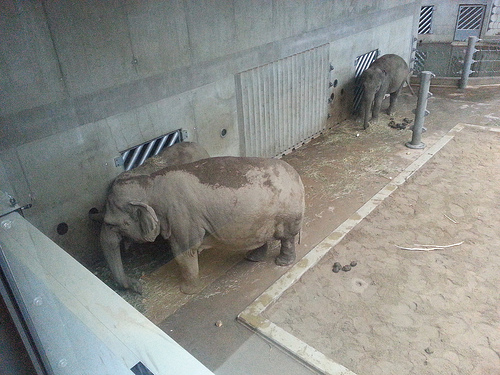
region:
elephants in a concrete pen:
[116, 52, 441, 296]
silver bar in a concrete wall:
[120, 133, 187, 163]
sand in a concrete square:
[320, 281, 495, 354]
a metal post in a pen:
[408, 71, 440, 151]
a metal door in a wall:
[233, 41, 335, 162]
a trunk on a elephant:
[96, 236, 128, 293]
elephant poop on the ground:
[317, 260, 364, 277]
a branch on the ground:
[398, 232, 475, 261]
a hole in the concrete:
[215, 122, 232, 141]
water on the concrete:
[318, 137, 396, 205]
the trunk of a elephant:
[91, 189, 142, 286]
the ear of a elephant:
[110, 193, 196, 250]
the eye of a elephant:
[96, 205, 145, 245]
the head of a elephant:
[85, 168, 194, 270]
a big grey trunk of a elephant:
[80, 204, 172, 316]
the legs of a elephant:
[164, 191, 227, 313]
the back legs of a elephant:
[239, 215, 310, 268]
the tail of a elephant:
[283, 205, 316, 262]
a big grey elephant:
[347, 38, 441, 148]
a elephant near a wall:
[78, 115, 343, 277]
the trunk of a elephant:
[343, 56, 409, 143]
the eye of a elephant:
[104, 191, 163, 258]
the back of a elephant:
[134, 140, 325, 249]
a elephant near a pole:
[331, 70, 437, 160]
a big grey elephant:
[116, 113, 409, 270]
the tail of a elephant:
[281, 171, 354, 267]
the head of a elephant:
[333, 43, 410, 140]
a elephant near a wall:
[303, 23, 443, 155]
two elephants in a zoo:
[34, 33, 454, 318]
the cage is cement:
[32, 39, 455, 304]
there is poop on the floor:
[30, 40, 480, 315]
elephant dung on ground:
[301, 241, 408, 312]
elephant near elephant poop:
[336, 42, 456, 154]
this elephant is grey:
[329, 50, 428, 156]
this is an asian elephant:
[49, 119, 343, 337]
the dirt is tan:
[255, 244, 394, 334]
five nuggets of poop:
[323, 240, 399, 285]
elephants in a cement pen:
[77, 57, 427, 302]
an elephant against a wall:
[86, 153, 307, 280]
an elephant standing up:
[361, 50, 408, 117]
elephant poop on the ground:
[328, 252, 364, 274]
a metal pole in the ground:
[408, 64, 433, 146]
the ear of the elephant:
[131, 195, 163, 245]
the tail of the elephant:
[403, 75, 417, 97]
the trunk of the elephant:
[102, 223, 133, 298]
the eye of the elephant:
[108, 218, 116, 227]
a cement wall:
[10, 204, 159, 364]